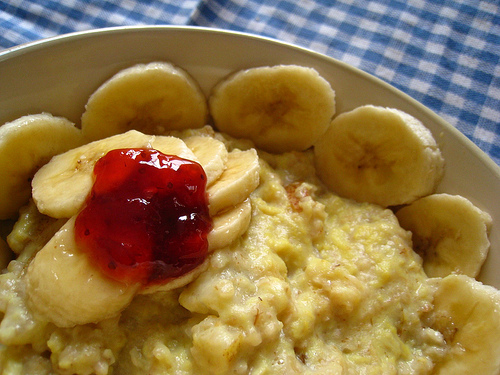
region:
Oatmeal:
[8, 137, 483, 368]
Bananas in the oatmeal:
[24, 56, 481, 346]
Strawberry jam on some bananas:
[68, 137, 228, 295]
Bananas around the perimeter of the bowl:
[7, 67, 422, 159]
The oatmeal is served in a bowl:
[8, 15, 498, 352]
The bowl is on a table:
[18, 2, 495, 358]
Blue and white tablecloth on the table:
[363, 7, 491, 74]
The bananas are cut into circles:
[312, 84, 443, 214]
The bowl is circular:
[16, 20, 485, 374]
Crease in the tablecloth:
[162, 0, 229, 24]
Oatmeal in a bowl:
[2, 145, 445, 373]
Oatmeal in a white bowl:
[4, 125, 459, 374]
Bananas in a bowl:
[1, 60, 496, 370]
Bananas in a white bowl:
[0, 60, 495, 373]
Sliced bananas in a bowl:
[0, 58, 496, 373]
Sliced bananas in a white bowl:
[2, 57, 498, 371]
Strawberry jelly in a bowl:
[70, 148, 225, 282]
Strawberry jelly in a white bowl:
[77, 145, 214, 288]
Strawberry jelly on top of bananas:
[72, 145, 212, 289]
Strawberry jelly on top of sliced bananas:
[71, 142, 215, 289]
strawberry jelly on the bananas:
[78, 144, 209, 284]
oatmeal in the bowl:
[251, 243, 332, 309]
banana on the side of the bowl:
[316, 103, 438, 189]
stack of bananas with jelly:
[32, 143, 253, 334]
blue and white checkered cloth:
[362, 27, 421, 61]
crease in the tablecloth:
[149, 3, 225, 28]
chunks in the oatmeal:
[191, 299, 266, 362]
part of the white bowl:
[458, 137, 480, 170]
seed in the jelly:
[80, 222, 95, 244]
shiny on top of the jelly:
[141, 150, 180, 172]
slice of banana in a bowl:
[68, 57, 208, 143]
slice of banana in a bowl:
[22, 118, 157, 217]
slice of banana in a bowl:
[0, 108, 87, 225]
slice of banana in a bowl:
[14, 196, 153, 330]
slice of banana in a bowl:
[205, 62, 337, 159]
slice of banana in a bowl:
[313, 105, 443, 207]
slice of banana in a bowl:
[389, 186, 498, 287]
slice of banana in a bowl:
[424, 271, 499, 373]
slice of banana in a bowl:
[207, 146, 268, 218]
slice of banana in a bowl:
[202, 193, 257, 257]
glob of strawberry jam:
[75, 149, 210, 280]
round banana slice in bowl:
[319, 103, 442, 206]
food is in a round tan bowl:
[6, 25, 490, 368]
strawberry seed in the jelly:
[104, 255, 121, 272]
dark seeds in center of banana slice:
[354, 160, 382, 175]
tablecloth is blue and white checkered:
[2, 2, 495, 29]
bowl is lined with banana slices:
[2, 59, 483, 209]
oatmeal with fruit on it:
[2, 23, 497, 370]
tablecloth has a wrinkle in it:
[178, 2, 220, 25]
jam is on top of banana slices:
[24, 131, 260, 308]